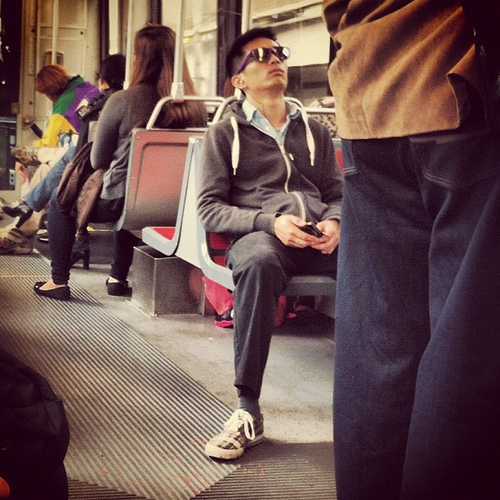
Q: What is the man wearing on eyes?
A: Sunglasses.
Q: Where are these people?
A: Subway.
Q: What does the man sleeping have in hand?
A: Cell phone.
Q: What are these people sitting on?
A: Chairs.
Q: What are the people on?
A: Train.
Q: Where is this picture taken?
A: A train.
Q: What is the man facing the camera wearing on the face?
A: Sunglasses.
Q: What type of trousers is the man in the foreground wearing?
A: Jeans.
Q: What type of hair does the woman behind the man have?
A: Long and brown.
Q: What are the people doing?
A: Riding.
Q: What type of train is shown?
A: Subway.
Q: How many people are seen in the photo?
A: Five.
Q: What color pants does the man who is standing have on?
A: Bluejeans.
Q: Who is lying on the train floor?
A: No one.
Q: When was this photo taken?
A: Daytime.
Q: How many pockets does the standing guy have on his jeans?
A: Two.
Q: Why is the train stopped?
A: At a station.